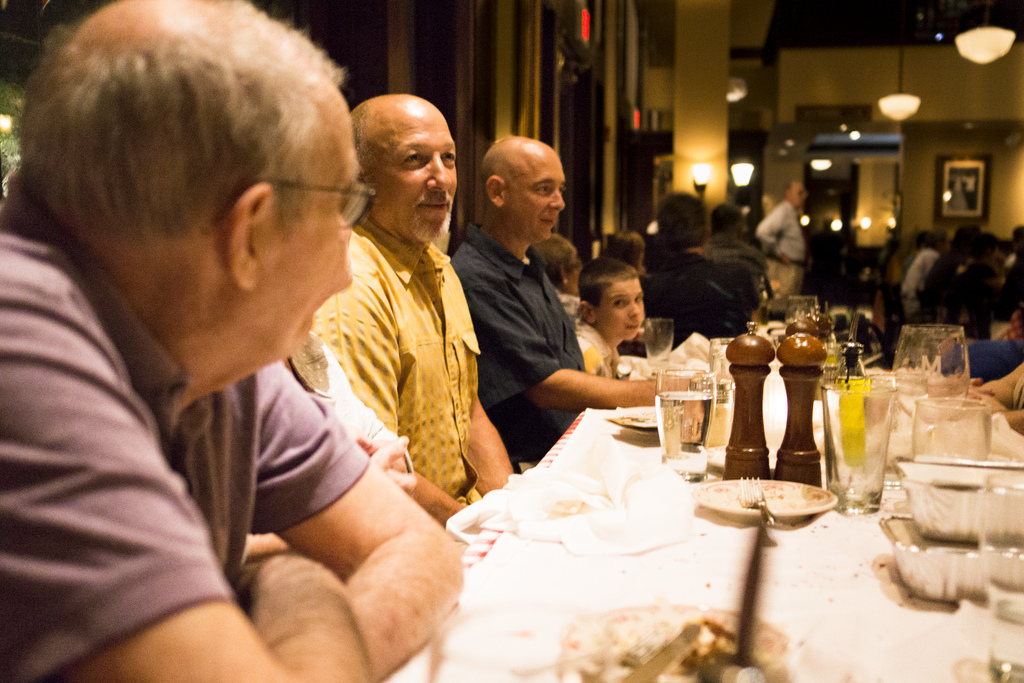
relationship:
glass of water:
[653, 367, 717, 473] [653, 367, 717, 473]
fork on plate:
[733, 474, 798, 533] [685, 453, 845, 539]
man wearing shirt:
[461, 136, 580, 245] [461, 228, 604, 393]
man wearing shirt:
[324, 82, 518, 438] [324, 222, 480, 438]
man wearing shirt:
[54, 49, 380, 378] [25, 313, 321, 626]